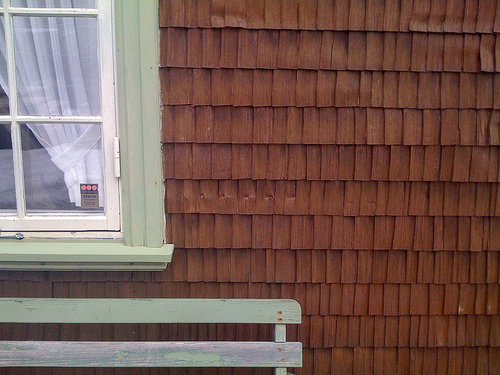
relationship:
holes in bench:
[271, 306, 285, 325] [0, 292, 305, 372]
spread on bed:
[2, 148, 70, 204] [2, 147, 104, 210]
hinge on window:
[111, 137, 131, 182] [5, 7, 192, 276]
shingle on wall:
[478, 33, 495, 73] [0, 1, 497, 373]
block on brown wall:
[164, 65, 199, 108] [0, 0, 499, 375]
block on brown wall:
[397, 73, 418, 107] [0, 0, 499, 375]